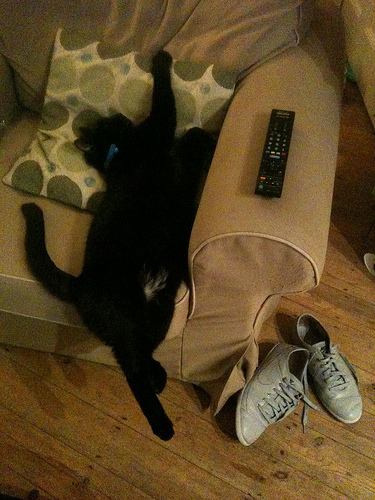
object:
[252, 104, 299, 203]
remote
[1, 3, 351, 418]
couch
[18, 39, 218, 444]
cat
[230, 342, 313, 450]
shoes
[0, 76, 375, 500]
floor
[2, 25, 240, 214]
pillow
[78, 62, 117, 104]
dots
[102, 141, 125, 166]
collar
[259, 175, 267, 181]
button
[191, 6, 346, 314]
arm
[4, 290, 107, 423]
shadow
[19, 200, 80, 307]
tail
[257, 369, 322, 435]
shoelaces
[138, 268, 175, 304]
hair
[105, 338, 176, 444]
legs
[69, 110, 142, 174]
head